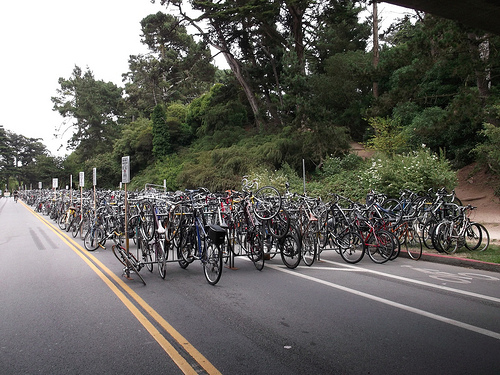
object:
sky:
[0, 0, 235, 163]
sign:
[120, 155, 130, 283]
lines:
[234, 235, 498, 339]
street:
[0, 186, 499, 372]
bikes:
[430, 203, 490, 252]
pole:
[93, 166, 101, 206]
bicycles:
[57, 206, 83, 233]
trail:
[446, 159, 498, 234]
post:
[121, 182, 130, 276]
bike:
[173, 204, 229, 284]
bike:
[310, 217, 365, 263]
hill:
[133, 124, 499, 238]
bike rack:
[99, 230, 147, 286]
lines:
[116, 285, 218, 373]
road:
[137, 257, 493, 372]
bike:
[228, 175, 285, 218]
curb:
[386, 244, 498, 276]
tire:
[464, 222, 490, 253]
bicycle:
[429, 205, 491, 256]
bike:
[98, 228, 151, 288]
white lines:
[274, 264, 498, 343]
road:
[17, 277, 117, 336]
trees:
[190, 0, 478, 186]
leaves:
[393, 59, 433, 101]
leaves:
[317, 35, 342, 85]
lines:
[14, 193, 239, 370]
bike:
[317, 215, 366, 264]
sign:
[92, 165, 97, 185]